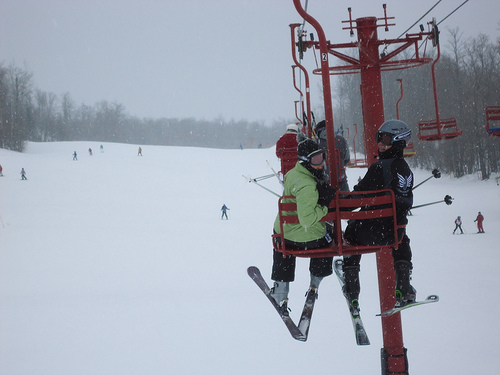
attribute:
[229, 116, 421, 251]
people — skiing, together, going, riding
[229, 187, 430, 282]
lift — red, empty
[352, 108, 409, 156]
pair — grey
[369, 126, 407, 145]
goggles — black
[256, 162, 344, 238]
jacket — green, wings, black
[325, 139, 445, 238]
jacket — black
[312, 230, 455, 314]
boots — white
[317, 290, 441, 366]
skis — gray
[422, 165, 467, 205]
poles — black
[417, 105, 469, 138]
life — empty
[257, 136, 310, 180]
suit — red, blue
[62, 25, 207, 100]
sky — cloudy, grey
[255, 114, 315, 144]
hat — white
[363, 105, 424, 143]
helmet — grey